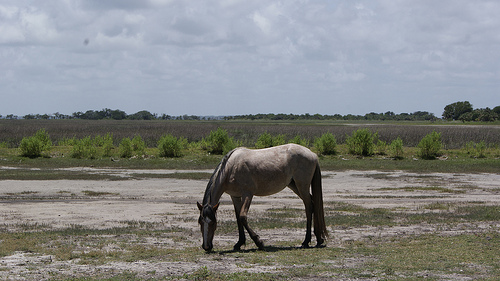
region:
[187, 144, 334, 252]
The horse shown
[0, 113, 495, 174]
The grass behind the horse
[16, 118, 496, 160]
The line of bushes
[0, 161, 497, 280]
The mostly dirt lot the horse is standing on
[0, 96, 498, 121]
The trees in the background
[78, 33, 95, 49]
The circular spec in the sky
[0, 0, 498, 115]
The clouds in the sky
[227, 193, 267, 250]
The front legs of the horse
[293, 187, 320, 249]
The back legs of the horse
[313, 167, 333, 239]
The tail of the horse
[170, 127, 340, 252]
the horse is standing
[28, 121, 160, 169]
the bush is green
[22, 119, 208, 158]
there are many bushes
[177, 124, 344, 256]
the horse is brown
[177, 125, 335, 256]
the horse is eating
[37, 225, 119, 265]
the grass is green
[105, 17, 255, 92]
the sky is cloudy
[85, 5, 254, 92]
the clouds are white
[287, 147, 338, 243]
the tail is long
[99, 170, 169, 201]
the dirt is brown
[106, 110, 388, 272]
horse grazing alone in a field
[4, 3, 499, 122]
cloudy overcast sky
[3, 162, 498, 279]
grass is sparse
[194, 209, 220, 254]
horse has a white marking down its nose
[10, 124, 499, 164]
small green bushes behind a horse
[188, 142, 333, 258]
horse has its neck bent down and its mouth close to the ground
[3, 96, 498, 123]
trees in the background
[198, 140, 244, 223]
horse has a dark colored mane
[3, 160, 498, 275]
field is not totally covered with grass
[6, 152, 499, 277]
grass on a field is patchy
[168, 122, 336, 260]
horse is skinny and pale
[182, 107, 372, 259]
a beautiful horse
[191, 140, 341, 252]
the horse is a dun color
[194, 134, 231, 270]
the horse has a black mane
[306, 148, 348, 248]
the horse has a black tail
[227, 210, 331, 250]
the lower part of the horse's legs are black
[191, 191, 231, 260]
the horse has a blaze on her face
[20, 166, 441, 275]
the horse is trying to graze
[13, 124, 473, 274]
the entire area is very sparse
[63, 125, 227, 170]
some greenery exists in the background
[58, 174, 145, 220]
this whole area looks veyr sandy and dry